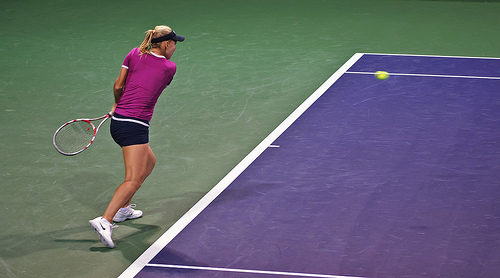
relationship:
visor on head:
[173, 29, 186, 43] [150, 25, 175, 59]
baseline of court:
[322, 67, 339, 92] [324, 84, 493, 276]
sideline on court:
[358, 50, 496, 61] [324, 84, 493, 276]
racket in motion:
[52, 112, 105, 159] [55, 97, 107, 118]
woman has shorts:
[87, 22, 180, 229] [111, 124, 145, 145]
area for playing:
[183, 27, 495, 275] [10, 21, 396, 247]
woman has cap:
[87, 22, 180, 229] [162, 31, 192, 43]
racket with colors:
[52, 112, 105, 159] [62, 118, 81, 126]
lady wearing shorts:
[87, 22, 180, 229] [111, 124, 145, 145]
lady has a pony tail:
[87, 22, 180, 229] [141, 28, 154, 53]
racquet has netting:
[52, 112, 105, 159] [63, 128, 84, 146]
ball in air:
[373, 69, 389, 81] [319, 36, 450, 120]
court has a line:
[183, 27, 495, 275] [338, 63, 348, 78]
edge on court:
[334, 62, 349, 80] [324, 84, 493, 276]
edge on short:
[107, 118, 150, 126] [111, 124, 145, 145]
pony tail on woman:
[141, 28, 154, 53] [87, 22, 180, 229]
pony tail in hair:
[141, 28, 154, 53] [145, 26, 169, 36]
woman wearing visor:
[87, 22, 180, 229] [173, 29, 186, 43]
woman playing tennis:
[87, 22, 180, 229] [10, 21, 396, 247]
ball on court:
[373, 69, 389, 81] [324, 84, 493, 276]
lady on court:
[87, 22, 180, 229] [324, 84, 493, 276]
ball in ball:
[373, 69, 389, 81] [373, 69, 389, 81]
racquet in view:
[52, 112, 105, 159] [40, 97, 112, 172]